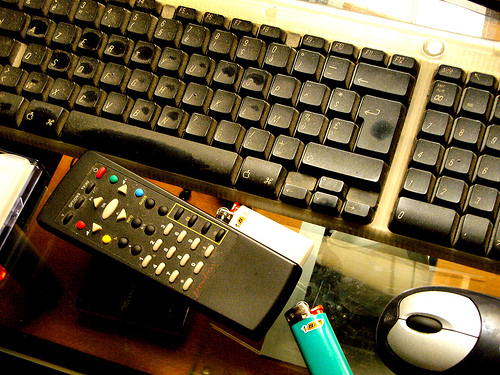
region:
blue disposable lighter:
[282, 300, 353, 373]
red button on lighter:
[309, 306, 326, 314]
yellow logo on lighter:
[301, 318, 323, 332]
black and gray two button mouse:
[372, 284, 498, 374]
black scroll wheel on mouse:
[407, 313, 442, 333]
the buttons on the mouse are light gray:
[390, 292, 480, 374]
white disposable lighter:
[215, 200, 314, 270]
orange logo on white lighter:
[232, 209, 249, 228]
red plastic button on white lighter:
[230, 200, 241, 212]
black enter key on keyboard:
[355, 94, 402, 157]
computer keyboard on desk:
[9, 5, 493, 232]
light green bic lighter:
[288, 286, 359, 366]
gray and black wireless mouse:
[373, 269, 487, 366]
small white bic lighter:
[203, 202, 325, 270]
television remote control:
[51, 151, 267, 331]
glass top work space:
[267, 222, 470, 374]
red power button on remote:
[88, 155, 113, 184]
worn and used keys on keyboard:
[23, 16, 402, 151]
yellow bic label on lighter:
[300, 316, 332, 339]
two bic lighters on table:
[210, 189, 367, 374]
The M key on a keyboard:
[272, 107, 285, 125]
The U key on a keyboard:
[187, 55, 204, 79]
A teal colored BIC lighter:
[291, 310, 355, 373]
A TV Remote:
[67, 162, 196, 291]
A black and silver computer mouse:
[380, 282, 498, 368]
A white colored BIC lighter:
[222, 199, 328, 254]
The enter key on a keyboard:
[369, 103, 390, 151]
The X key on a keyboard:
[48, 80, 75, 104]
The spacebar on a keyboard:
[100, 124, 200, 168]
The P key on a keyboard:
[267, 79, 297, 98]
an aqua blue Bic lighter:
[280, 302, 357, 373]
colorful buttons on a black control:
[37, 150, 306, 334]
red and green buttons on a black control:
[92, 166, 121, 182]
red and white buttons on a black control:
[70, 219, 106, 234]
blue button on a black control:
[130, 186, 147, 198]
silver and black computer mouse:
[373, 288, 498, 373]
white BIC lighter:
[206, 203, 313, 267]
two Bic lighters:
[209, 201, 356, 373]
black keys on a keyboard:
[3, 1, 495, 254]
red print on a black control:
[184, 258, 234, 299]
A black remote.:
[27, 144, 299, 340]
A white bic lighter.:
[210, 197, 324, 270]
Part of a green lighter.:
[273, 294, 357, 373]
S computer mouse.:
[380, 274, 499, 373]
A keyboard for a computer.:
[6, 0, 498, 139]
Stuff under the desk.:
[0, 289, 175, 373]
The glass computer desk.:
[328, 252, 405, 292]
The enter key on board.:
[357, 92, 409, 161]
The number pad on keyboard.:
[392, 108, 498, 243]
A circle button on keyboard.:
[411, 37, 450, 65]